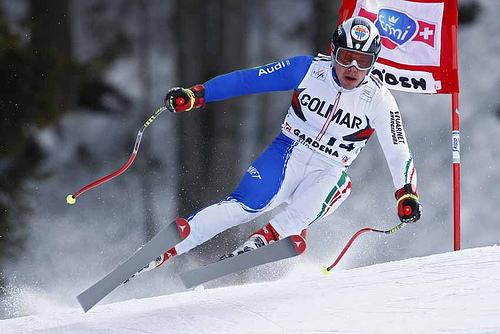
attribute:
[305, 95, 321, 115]
letter — black 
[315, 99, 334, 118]
letter — black 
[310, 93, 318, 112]
letter — black 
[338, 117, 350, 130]
letter — black 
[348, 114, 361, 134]
letter — black 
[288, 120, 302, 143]
letter — black 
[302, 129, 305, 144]
letter — black 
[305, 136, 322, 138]
letter — black 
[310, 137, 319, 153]
letter — black 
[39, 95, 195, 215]
ski poles — angled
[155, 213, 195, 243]
tip — red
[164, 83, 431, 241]
gloves — black, red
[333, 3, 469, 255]
flags — gate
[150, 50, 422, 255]
outfit — white, blue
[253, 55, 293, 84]
audi — sponsor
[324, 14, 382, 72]
helmet — black, silver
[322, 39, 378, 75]
googles — orange 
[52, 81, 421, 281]
poles — bent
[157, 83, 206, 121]
glove — black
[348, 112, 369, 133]
letter r — black, capital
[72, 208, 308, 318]
skis — gray, red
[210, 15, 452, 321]
person — skiing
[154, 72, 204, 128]
hand — skiers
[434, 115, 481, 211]
pole — red